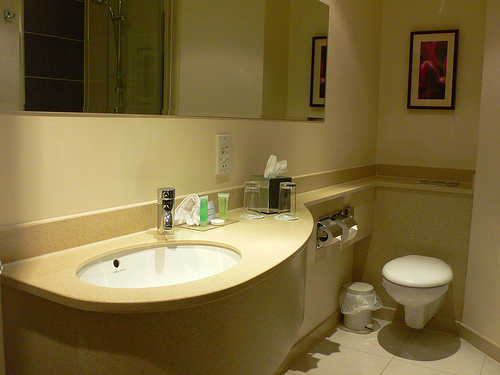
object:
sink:
[74, 238, 252, 290]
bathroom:
[0, 0, 498, 374]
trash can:
[338, 280, 378, 333]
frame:
[405, 29, 460, 110]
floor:
[279, 315, 499, 374]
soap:
[210, 218, 225, 228]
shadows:
[310, 338, 343, 356]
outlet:
[214, 133, 232, 183]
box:
[247, 172, 297, 215]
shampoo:
[197, 192, 209, 228]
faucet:
[155, 185, 175, 235]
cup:
[275, 182, 298, 222]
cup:
[241, 184, 263, 220]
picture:
[403, 30, 458, 112]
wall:
[349, 0, 486, 336]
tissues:
[261, 155, 289, 179]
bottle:
[197, 196, 209, 228]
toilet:
[380, 253, 454, 331]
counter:
[0, 201, 314, 315]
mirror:
[19, 0, 327, 123]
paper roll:
[317, 220, 343, 247]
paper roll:
[333, 216, 361, 245]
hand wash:
[217, 193, 229, 222]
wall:
[0, 0, 378, 374]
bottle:
[215, 191, 227, 224]